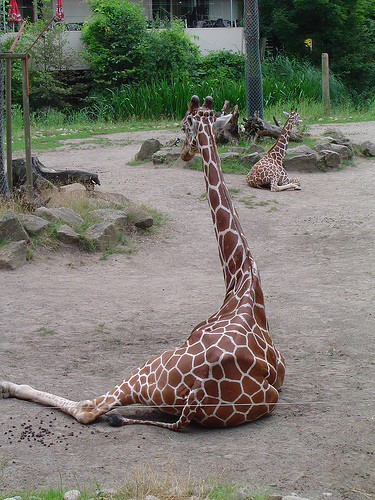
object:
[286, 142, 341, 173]
boulder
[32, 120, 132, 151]
grass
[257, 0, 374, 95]
trees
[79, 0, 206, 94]
bush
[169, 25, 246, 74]
wall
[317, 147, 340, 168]
rock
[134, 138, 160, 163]
rock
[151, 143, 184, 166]
rock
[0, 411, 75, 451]
droppings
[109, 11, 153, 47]
leaves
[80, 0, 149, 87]
tree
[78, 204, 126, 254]
ground rocks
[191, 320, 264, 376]
pattern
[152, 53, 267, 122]
plants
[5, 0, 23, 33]
umbrella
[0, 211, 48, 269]
big rock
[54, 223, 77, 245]
big rock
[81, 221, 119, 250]
big rock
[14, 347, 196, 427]
leg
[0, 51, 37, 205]
metal structure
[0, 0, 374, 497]
zoo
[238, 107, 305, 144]
tree stump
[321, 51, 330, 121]
post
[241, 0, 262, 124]
fence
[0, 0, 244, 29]
patio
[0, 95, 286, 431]
animal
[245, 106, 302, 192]
animal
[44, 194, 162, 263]
grass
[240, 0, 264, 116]
tree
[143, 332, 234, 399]
lines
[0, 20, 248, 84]
porch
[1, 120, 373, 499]
dirt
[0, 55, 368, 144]
enclosure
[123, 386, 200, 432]
tail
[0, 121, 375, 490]
ground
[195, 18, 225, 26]
furniture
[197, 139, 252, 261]
neck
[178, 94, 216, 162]
head